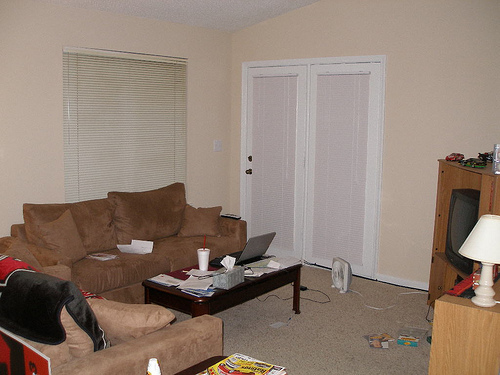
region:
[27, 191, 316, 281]
the couch is brown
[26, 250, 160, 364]
the couch is brown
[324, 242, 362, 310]
a small white box fan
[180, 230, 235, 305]
white cup on table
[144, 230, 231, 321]
white cup on table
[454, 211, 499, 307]
Small table lamp sitting on a table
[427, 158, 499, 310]
TV stand sitting in the corner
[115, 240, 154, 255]
Paperwork sitting on the couch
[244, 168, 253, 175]
A doorknob to open the door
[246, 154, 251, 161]
Deadbolt lock to lock the door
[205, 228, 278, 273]
Laptop computer opened on the table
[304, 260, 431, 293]
Wire attached to baseboard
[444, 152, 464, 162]
Diecast NASCAR sitting on the TV stand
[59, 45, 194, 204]
Large set of vertical blinds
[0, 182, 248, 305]
Brown sofa sitting in the living room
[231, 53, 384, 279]
The door is white.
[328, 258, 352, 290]
The fan is on the floor.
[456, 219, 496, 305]
The lamp is white.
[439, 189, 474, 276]
The TV is off.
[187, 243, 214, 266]
The cup is on the table.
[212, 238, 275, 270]
The computer is on the table.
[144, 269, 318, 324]
The table is brown.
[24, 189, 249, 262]
The couch is tan.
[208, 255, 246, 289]
Tissues are on the table.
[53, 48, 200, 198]
The blinds are down.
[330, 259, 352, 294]
Small space heater on the floor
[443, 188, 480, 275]
Television in TV stand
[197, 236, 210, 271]
Styrofoam cup on coffee table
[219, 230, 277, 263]
Laptop computer on coffee table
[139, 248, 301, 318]
Coffee table in front of a couch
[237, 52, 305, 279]
Doorway into messy room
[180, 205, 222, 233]
Brown throw pillow on the couch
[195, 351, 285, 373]
Stack of magazines on an end table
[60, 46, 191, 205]
Large window covered by blinds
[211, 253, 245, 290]
Box of tissues on coffee table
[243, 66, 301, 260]
A white door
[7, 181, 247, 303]
A large brown couch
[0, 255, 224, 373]
A large brown couch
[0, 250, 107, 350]
A black and red blanket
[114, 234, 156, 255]
A piece of paper on a couch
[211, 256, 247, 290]
A box of tissues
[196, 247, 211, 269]
A white Styrofoam cup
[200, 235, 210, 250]
A red straw in a cup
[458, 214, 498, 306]
A small white lamp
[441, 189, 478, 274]
A small black television